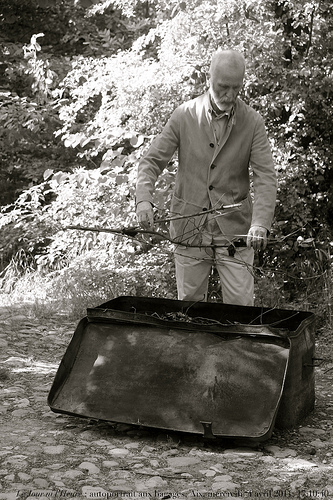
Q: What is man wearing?
A: Blazer.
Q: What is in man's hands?
A: Sticks.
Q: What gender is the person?
A: Male.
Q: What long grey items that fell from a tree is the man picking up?
A: Branches.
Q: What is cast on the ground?
A: Shadow.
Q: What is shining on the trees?
A: Sunlight.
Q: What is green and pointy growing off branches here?
A: Leaves.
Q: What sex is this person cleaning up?
A: Male.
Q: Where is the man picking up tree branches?
A: Is outside.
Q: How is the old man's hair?
A: Thinning.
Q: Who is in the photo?
A: A man.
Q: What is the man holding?
A: A stick.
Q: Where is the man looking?
A: Down.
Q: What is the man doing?
A: Breaking sticks.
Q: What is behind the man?
A: Trees.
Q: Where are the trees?
A: Behind the man.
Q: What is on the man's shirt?
A: Buttons.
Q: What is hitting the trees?
A: Light.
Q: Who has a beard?
A: The man.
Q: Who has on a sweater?
A: The man.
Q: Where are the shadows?
A: On the ground.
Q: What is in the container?
A: Twigs.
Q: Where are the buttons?
A: On the sweater.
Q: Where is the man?
A: In nature.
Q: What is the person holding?
A: Sticks.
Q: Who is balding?
A: The old man.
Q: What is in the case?
A: The twigs.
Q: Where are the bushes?
A: Behind the man.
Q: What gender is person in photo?
A: Male.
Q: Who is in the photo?
A: A man.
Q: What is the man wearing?
A: Clothes.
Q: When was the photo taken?
A: Daytime.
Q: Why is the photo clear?
A: Its during the day.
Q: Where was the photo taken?
A: On a path.